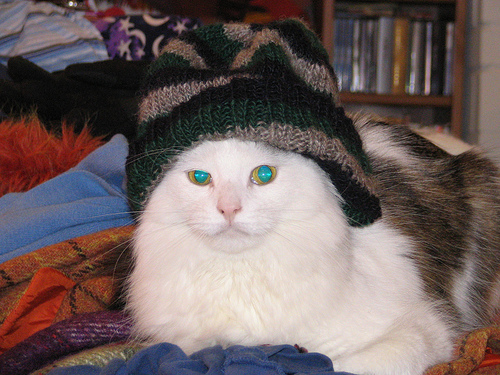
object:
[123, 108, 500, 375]
cat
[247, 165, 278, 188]
eyes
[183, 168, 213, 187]
eye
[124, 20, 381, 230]
hat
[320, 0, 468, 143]
bookcase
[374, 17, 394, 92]
books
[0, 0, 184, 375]
bed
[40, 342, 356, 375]
blankets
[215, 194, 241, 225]
nose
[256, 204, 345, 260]
wiskers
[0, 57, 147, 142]
blankets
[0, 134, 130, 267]
clothing